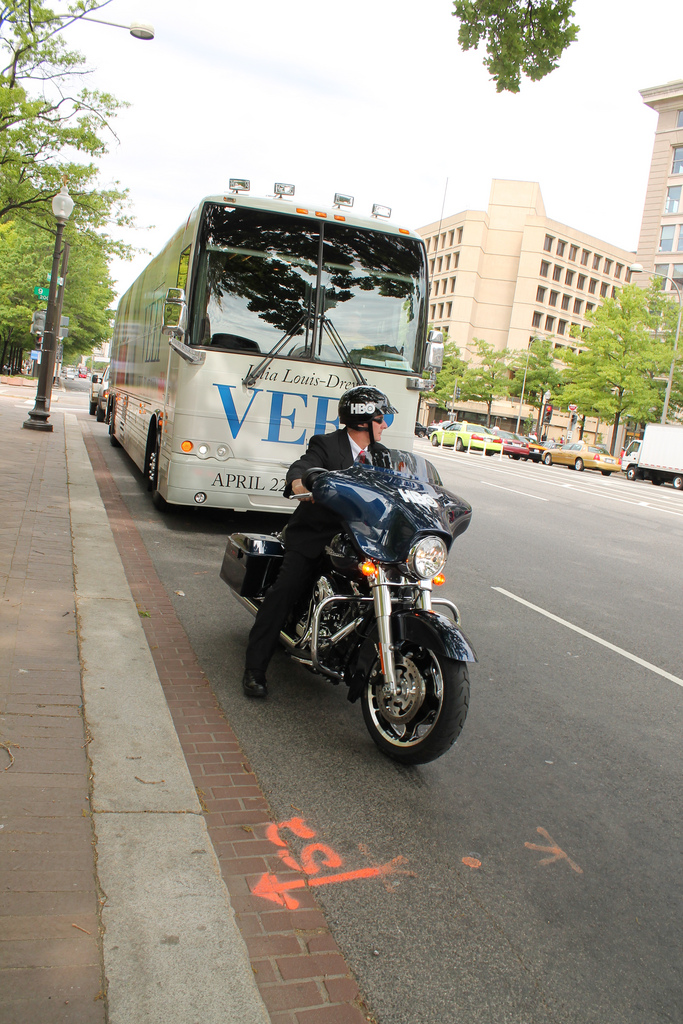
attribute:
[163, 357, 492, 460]
writing — blue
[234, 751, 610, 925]
writing — orange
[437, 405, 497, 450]
car — yellow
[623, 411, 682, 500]
truck — white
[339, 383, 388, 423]
helmet — black